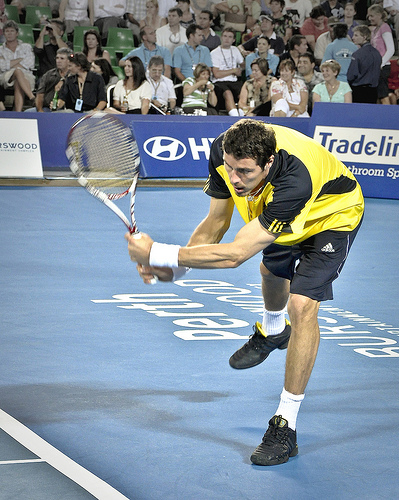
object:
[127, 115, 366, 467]
man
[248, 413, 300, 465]
shoes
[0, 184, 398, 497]
court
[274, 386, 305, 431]
sock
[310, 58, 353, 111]
spectators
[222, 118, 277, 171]
hair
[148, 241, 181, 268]
wrist band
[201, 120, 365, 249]
shirt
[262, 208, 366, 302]
shorts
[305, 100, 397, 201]
advertisement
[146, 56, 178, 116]
man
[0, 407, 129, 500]
line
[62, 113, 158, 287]
racket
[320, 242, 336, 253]
logo